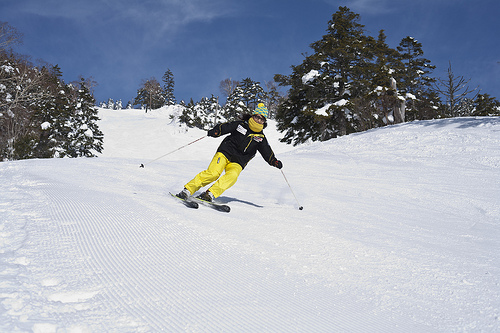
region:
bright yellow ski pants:
[179, 147, 248, 210]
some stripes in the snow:
[51, 183, 196, 322]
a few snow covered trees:
[178, 73, 260, 138]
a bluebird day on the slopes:
[64, 53, 486, 318]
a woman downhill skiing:
[73, 78, 391, 269]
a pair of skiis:
[121, 175, 250, 222]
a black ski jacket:
[178, 114, 294, 179]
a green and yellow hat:
[238, 93, 286, 124]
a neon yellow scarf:
[240, 118, 270, 138]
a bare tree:
[437, 65, 477, 124]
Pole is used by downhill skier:
[134, 123, 208, 173]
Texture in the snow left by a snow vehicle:
[60, 186, 131, 272]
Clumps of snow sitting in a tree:
[300, 65, 328, 88]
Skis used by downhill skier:
[164, 181, 244, 221]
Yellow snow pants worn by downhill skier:
[175, 148, 249, 205]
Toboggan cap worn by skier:
[245, 100, 274, 120]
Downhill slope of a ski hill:
[96, 110, 461, 332]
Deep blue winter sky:
[89, 14, 283, 62]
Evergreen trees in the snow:
[281, 2, 415, 154]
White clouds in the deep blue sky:
[145, 1, 217, 38]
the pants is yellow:
[210, 171, 217, 182]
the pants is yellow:
[220, 168, 227, 185]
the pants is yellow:
[227, 168, 233, 193]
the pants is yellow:
[208, 162, 218, 183]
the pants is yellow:
[209, 174, 217, 189]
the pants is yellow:
[202, 168, 212, 188]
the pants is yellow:
[204, 163, 221, 199]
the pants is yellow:
[222, 171, 232, 194]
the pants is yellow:
[227, 173, 237, 178]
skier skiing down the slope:
[141, 78, 297, 272]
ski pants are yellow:
[160, 151, 254, 217]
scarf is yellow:
[241, 109, 301, 135]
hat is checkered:
[241, 88, 300, 116]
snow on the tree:
[288, 62, 444, 126]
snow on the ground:
[70, 243, 382, 316]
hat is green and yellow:
[245, 94, 285, 120]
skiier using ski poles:
[115, 122, 331, 225]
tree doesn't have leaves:
[424, 55, 482, 125]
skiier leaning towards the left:
[190, 95, 290, 251]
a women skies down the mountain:
[164, 94, 279, 224]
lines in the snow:
[168, 249, 258, 324]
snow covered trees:
[288, 57, 354, 122]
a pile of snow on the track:
[9, 225, 52, 332]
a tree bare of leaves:
[429, 53, 479, 128]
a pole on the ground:
[273, 154, 310, 219]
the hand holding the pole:
[268, 154, 283, 171]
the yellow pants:
[181, 149, 248, 199]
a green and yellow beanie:
[243, 99, 275, 120]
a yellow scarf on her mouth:
[243, 110, 272, 136]